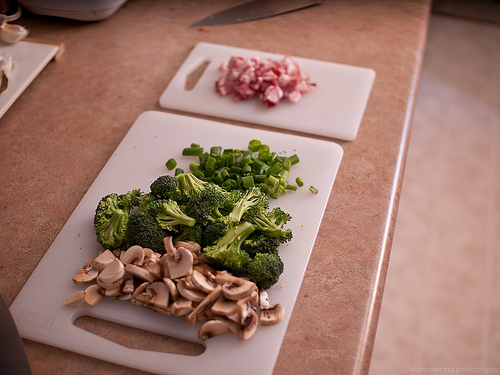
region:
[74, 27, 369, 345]
food on chopping board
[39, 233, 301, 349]
mushrooms on the board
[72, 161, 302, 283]
broccoli florets on the board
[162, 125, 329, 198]
chopped chives on the board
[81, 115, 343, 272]
the board is white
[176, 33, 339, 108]
chopped up meat on the board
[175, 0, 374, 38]
the knife is sharp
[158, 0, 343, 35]
the knife is silver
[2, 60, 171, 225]
the table is tan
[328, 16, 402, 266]
the table is marble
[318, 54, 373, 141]
A portion of a white plate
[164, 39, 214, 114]
A portion of a white plate, with a handle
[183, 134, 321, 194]
Cut and Diced Vegetables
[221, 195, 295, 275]
A set of brocoli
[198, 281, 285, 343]
Chopped anchovies on a cutting plate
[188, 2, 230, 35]
The edge of a cutting knife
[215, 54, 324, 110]
A set of cut vegetables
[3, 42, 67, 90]
The edge of a cutting plate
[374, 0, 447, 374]
The marble edge of a counter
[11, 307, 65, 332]
The logo of a cutting plate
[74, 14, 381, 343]
vegetables on chopping boards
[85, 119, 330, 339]
the vegetables are chopped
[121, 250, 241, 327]
these are chopped mushrooms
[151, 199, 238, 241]
this is chopped broccoli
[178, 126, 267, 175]
these are chopped chives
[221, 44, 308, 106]
these are chopped onions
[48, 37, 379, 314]
the chopping boards are plastic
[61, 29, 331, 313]
the chopping boards are white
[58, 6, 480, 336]
the countertop is pink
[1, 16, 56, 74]
this is a clove of garlic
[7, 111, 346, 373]
Chopped broccoli on a white cutting board.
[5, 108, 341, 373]
Mushrooms on a white cutting board.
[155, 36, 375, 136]
Diced meat on a white cutting board.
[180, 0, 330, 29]
The edge of a knife.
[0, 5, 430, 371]
White cutting boards on a countertop.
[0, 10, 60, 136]
Garlic cloves ontop of a cutting board.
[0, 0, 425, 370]
A tan marbled countertop.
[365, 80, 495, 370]
Tan marbled flooring.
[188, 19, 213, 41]
A small piece of meat on the countertop.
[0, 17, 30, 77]
Two unpeeled galic cloves.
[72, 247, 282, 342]
a pile of chopped up mushrooms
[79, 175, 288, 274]
a pile of chopped up broccoli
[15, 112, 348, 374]
a plastic cutting board on the counter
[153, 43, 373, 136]
a smaller cutting board on the counter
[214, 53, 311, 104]
a pile of meat sitting on the little cutting board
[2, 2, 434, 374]
the counter all the boards are sitting on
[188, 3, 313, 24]
the knife sitting on the counter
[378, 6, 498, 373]
the floor next to the counter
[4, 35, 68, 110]
another cutting board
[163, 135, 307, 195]
a little pile of cut up french onions